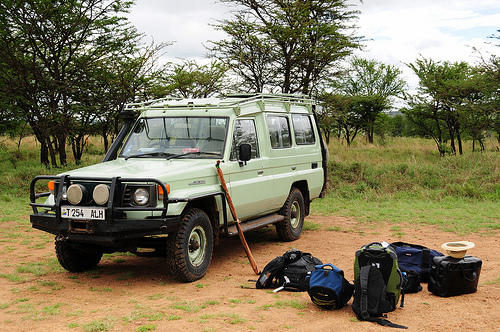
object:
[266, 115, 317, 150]
windows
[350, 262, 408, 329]
backpack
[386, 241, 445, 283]
bag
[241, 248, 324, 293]
bag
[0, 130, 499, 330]
ground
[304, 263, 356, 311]
back pack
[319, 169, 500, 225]
grass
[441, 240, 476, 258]
hat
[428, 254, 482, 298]
bag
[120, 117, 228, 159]
windshield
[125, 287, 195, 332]
grass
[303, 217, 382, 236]
grass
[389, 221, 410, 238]
grass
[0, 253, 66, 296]
grass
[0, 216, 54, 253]
grass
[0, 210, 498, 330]
dirt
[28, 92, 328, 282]
jeep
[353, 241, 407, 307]
backpack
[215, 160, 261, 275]
umbrella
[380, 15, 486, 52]
cloudy sky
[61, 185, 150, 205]
headlight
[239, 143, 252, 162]
mirror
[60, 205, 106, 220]
license plate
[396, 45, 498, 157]
tree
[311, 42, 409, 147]
tree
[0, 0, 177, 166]
tree